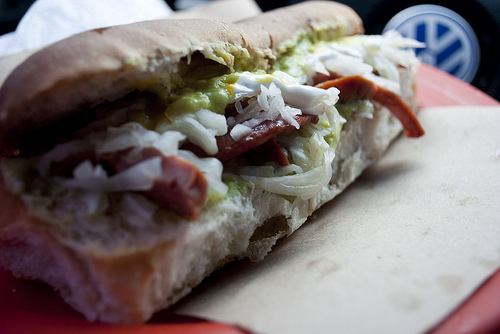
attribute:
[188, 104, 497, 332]
napkin — used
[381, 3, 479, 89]
logo — silver, blue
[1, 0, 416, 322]
bread — cut in half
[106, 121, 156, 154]
veggies — red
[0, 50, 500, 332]
plate — orange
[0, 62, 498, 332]
tray — plastic, red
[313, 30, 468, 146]
sticker — Volkswagen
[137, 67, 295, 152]
spoonful — avocado sauce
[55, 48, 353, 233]
sandwich — sub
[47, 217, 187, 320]
bread — brown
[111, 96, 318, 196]
veggies — white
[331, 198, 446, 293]
paper — white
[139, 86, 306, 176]
cheese — grated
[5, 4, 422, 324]
hoagie sandwich — fresh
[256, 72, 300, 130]
onions — diced